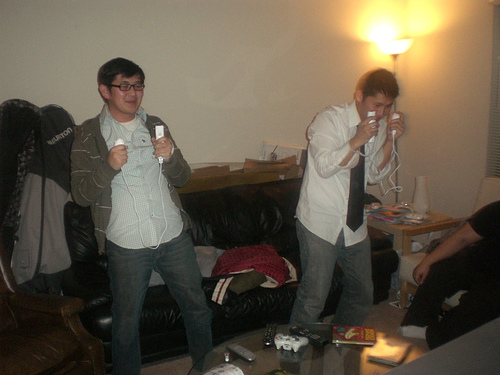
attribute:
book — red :
[330, 319, 379, 352]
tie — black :
[343, 120, 365, 234]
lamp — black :
[370, 26, 452, 211]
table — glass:
[238, 287, 449, 369]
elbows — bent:
[298, 143, 396, 187]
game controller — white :
[272, 330, 308, 354]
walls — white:
[2, 2, 499, 199]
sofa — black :
[57, 166, 404, 370]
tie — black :
[346, 127, 370, 243]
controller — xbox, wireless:
[271, 330, 311, 354]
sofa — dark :
[80, 161, 398, 372]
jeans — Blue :
[105, 238, 215, 373]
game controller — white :
[149, 119, 174, 173]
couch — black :
[63, 176, 399, 373]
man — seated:
[398, 192, 498, 351]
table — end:
[361, 197, 463, 307]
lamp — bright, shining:
[361, 3, 451, 90]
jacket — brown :
[68, 110, 193, 257]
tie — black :
[345, 143, 365, 233]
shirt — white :
[293, 100, 387, 246]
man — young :
[26, 34, 259, 374]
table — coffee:
[135, 318, 425, 373]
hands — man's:
[358, 105, 407, 147]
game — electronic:
[362, 114, 428, 181]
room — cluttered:
[8, 5, 488, 373]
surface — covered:
[360, 189, 467, 245]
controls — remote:
[360, 105, 413, 193]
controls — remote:
[354, 109, 406, 165]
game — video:
[103, 115, 418, 186]